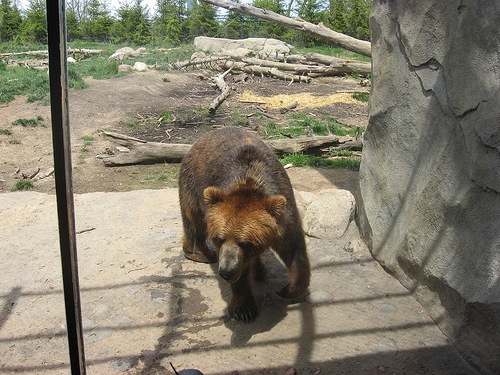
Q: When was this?
A: Daytime.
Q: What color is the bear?
A: Brown.